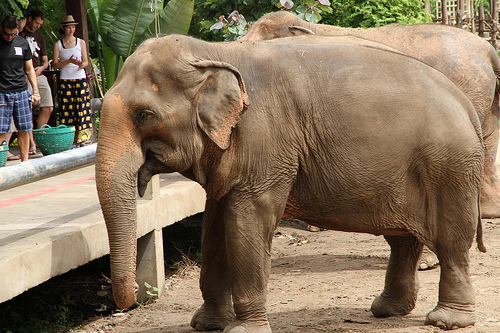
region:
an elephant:
[142, 38, 454, 290]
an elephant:
[177, 30, 358, 204]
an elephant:
[207, 66, 371, 299]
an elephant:
[213, 112, 346, 244]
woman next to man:
[55, 13, 92, 144]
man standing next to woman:
[20, 10, 51, 120]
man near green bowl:
[0, 20, 40, 160]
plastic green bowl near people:
[30, 120, 71, 155]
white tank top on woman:
[55, 32, 85, 77]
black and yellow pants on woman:
[55, 75, 90, 140]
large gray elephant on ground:
[90, 32, 480, 327]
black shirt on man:
[0, 31, 30, 87]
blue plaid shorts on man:
[0, 90, 30, 130]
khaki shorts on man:
[25, 73, 55, 108]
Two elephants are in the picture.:
[93, 7, 497, 329]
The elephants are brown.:
[94, 8, 496, 331]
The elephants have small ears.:
[178, 41, 270, 159]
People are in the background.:
[2, 11, 102, 167]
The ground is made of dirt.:
[296, 269, 358, 331]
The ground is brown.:
[298, 267, 348, 329]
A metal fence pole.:
[3, 142, 102, 196]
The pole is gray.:
[2, 142, 103, 195]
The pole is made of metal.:
[1, 139, 111, 204]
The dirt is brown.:
[291, 259, 360, 330]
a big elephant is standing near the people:
[81, 34, 478, 311]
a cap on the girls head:
[51, 12, 94, 147]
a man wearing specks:
[1, 14, 26, 49]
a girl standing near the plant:
[52, 13, 92, 147]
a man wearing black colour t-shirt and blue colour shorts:
[2, 20, 37, 166]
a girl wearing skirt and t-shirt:
[52, 11, 101, 142]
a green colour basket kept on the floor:
[31, 116, 81, 160]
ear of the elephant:
[187, 47, 272, 184]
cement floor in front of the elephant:
[11, 172, 80, 251]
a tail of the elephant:
[459, 89, 499, 258]